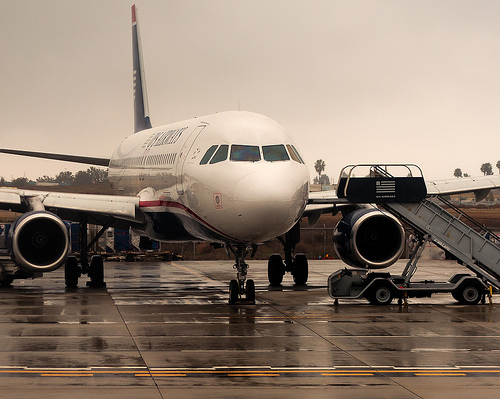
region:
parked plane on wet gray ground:
[4, 256, 497, 394]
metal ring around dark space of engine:
[12, 211, 68, 268]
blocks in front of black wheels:
[60, 245, 310, 311]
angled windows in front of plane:
[197, 140, 302, 165]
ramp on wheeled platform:
[327, 157, 494, 303]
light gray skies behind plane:
[1, 5, 496, 185]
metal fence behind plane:
[85, 220, 340, 257]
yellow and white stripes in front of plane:
[0, 360, 490, 375]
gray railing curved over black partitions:
[333, 160, 425, 198]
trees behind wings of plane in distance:
[0, 155, 499, 190]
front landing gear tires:
[228, 278, 256, 300]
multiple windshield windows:
[198, 144, 302, 164]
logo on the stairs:
[373, 178, 398, 200]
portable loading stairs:
[337, 160, 492, 305]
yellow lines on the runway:
[6, 365, 496, 376]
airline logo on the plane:
[143, 127, 183, 146]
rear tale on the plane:
[127, 5, 151, 128]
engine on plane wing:
[9, 213, 69, 268]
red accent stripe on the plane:
[139, 190, 237, 237]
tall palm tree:
[315, 158, 325, 184]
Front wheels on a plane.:
[227, 276, 259, 301]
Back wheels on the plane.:
[58, 250, 108, 292]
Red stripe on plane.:
[135, 193, 240, 243]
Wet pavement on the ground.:
[1, 258, 494, 393]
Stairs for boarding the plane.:
[338, 162, 498, 304]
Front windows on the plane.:
[197, 143, 303, 167]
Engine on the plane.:
[332, 201, 406, 270]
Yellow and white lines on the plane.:
[5, 355, 497, 382]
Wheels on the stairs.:
[329, 271, 491, 306]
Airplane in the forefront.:
[2, 3, 497, 310]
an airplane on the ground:
[0, 3, 499, 291]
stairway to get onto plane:
[333, 160, 498, 309]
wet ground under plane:
[1, 257, 499, 397]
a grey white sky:
[1, 0, 498, 182]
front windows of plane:
[196, 141, 306, 166]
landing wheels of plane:
[61, 248, 311, 307]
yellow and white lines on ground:
[0, 360, 498, 378]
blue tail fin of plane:
[129, 2, 151, 132]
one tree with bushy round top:
[313, 156, 328, 192]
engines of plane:
[6, 208, 407, 274]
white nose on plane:
[222, 127, 290, 230]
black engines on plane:
[10, 174, 418, 271]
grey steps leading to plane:
[380, 174, 499, 304]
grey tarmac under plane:
[107, 277, 319, 397]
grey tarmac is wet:
[58, 284, 441, 391]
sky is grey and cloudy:
[235, 6, 433, 133]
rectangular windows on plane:
[200, 121, 316, 181]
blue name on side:
[140, 122, 207, 194]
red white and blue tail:
[110, 11, 187, 159]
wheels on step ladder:
[332, 265, 498, 325]